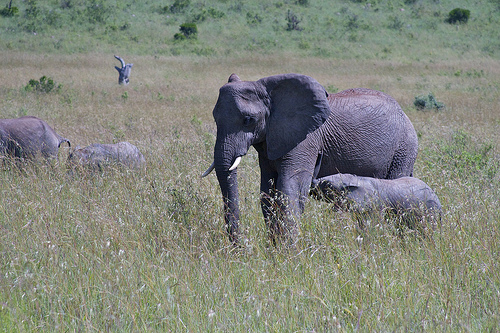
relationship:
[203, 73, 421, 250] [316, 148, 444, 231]
elephant by elephant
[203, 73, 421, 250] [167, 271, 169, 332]
elephant in grass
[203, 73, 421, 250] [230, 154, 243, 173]
elephant has tusks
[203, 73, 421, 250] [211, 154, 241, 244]
elephant has trunk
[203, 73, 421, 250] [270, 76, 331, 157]
elephant has ear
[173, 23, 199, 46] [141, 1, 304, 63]
bushes are on hill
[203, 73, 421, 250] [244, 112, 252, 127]
elephant has eye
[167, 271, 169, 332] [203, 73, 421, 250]
grass surrounds elephant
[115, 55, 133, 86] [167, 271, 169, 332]
tree in grass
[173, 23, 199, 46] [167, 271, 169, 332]
bushes are in grass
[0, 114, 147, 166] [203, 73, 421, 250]
elephants are far from elephant